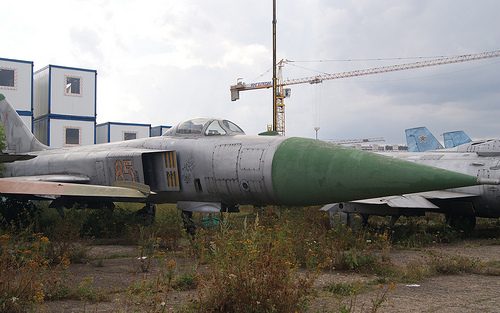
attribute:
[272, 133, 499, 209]
nose — green, pointy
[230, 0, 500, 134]
crane — large, huge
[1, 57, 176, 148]
rectangle boxes — white, cubed, stacked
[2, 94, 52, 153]
tail — blue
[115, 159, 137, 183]
number 85 — brown, fading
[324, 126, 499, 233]
jets — out of service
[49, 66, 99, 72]
trim — blue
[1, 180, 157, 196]
red paint — fading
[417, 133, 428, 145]
star — red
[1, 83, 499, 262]
plane — old